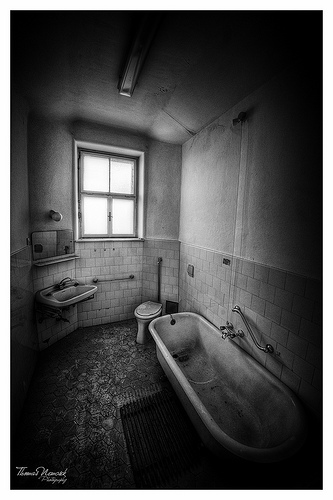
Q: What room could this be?
A: It is a bathroom.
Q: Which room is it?
A: It is a bathroom.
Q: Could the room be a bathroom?
A: Yes, it is a bathroom.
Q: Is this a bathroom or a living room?
A: It is a bathroom.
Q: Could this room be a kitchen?
A: No, it is a bathroom.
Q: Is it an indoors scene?
A: Yes, it is indoors.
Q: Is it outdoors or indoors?
A: It is indoors.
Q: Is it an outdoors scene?
A: No, it is indoors.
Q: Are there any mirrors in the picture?
A: Yes, there is a mirror.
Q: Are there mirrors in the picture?
A: Yes, there is a mirror.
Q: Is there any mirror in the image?
A: Yes, there is a mirror.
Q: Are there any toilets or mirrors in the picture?
A: Yes, there is a mirror.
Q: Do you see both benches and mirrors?
A: No, there is a mirror but no benches.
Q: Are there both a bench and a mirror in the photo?
A: No, there is a mirror but no benches.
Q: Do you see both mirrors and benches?
A: No, there is a mirror but no benches.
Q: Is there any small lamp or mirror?
A: Yes, there is a small mirror.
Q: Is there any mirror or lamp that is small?
A: Yes, the mirror is small.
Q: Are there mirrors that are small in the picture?
A: Yes, there is a small mirror.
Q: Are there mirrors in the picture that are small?
A: Yes, there is a mirror that is small.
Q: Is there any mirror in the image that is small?
A: Yes, there is a mirror that is small.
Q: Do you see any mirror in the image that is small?
A: Yes, there is a mirror that is small.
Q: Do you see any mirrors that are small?
A: Yes, there is a mirror that is small.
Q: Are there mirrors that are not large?
A: Yes, there is a small mirror.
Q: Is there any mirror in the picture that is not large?
A: Yes, there is a small mirror.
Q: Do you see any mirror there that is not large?
A: Yes, there is a small mirror.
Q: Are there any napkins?
A: No, there are no napkins.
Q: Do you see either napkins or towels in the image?
A: No, there are no napkins or towels.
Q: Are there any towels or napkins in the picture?
A: No, there are no napkins or towels.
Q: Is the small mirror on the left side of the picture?
A: Yes, the mirror is on the left of the image.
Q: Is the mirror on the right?
A: No, the mirror is on the left of the image.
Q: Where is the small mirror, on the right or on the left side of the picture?
A: The mirror is on the left of the image.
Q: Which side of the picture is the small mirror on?
A: The mirror is on the left of the image.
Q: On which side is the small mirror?
A: The mirror is on the left of the image.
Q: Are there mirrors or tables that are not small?
A: No, there is a mirror but it is small.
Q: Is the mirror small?
A: Yes, the mirror is small.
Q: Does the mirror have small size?
A: Yes, the mirror is small.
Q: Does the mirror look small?
A: Yes, the mirror is small.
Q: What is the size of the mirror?
A: The mirror is small.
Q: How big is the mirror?
A: The mirror is small.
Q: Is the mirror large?
A: No, the mirror is small.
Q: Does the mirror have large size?
A: No, the mirror is small.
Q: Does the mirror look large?
A: No, the mirror is small.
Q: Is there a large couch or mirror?
A: No, there is a mirror but it is small.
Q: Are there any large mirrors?
A: No, there is a mirror but it is small.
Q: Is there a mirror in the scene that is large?
A: No, there is a mirror but it is small.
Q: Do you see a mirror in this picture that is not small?
A: No, there is a mirror but it is small.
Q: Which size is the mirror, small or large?
A: The mirror is small.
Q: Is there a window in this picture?
A: Yes, there is a window.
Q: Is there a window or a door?
A: Yes, there is a window.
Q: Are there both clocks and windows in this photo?
A: No, there is a window but no clocks.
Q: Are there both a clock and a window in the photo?
A: No, there is a window but no clocks.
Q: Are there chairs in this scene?
A: No, there are no chairs.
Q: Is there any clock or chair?
A: No, there are no chairs or clocks.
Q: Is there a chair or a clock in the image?
A: No, there are no chairs or clocks.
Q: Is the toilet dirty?
A: Yes, the toilet is dirty.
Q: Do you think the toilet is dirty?
A: Yes, the toilet is dirty.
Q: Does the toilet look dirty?
A: Yes, the toilet is dirty.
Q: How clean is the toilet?
A: The toilet is dirty.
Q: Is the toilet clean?
A: No, the toilet is dirty.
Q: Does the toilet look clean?
A: No, the toilet is dirty.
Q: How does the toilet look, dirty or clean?
A: The toilet is dirty.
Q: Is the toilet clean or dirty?
A: The toilet is dirty.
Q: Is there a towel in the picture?
A: No, there are no towels.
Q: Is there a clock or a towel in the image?
A: No, there are no towels or clocks.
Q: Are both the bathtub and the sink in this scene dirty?
A: Yes, both the bathtub and the sink are dirty.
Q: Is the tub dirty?
A: Yes, the tub is dirty.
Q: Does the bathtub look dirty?
A: Yes, the bathtub is dirty.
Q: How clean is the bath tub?
A: The bath tub is dirty.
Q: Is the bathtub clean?
A: No, the bathtub is dirty.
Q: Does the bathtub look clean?
A: No, the bathtub is dirty.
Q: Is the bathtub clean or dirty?
A: The bathtub is dirty.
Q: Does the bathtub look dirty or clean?
A: The bathtub is dirty.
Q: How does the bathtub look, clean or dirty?
A: The bathtub is dirty.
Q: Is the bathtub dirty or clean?
A: The bathtub is dirty.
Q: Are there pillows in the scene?
A: No, there are no pillows.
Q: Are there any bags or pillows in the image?
A: No, there are no pillows or bags.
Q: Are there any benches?
A: No, there are no benches.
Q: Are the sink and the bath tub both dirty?
A: Yes, both the sink and the bath tub are dirty.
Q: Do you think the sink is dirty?
A: Yes, the sink is dirty.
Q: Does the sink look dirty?
A: Yes, the sink is dirty.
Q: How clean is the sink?
A: The sink is dirty.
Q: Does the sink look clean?
A: No, the sink is dirty.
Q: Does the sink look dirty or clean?
A: The sink is dirty.